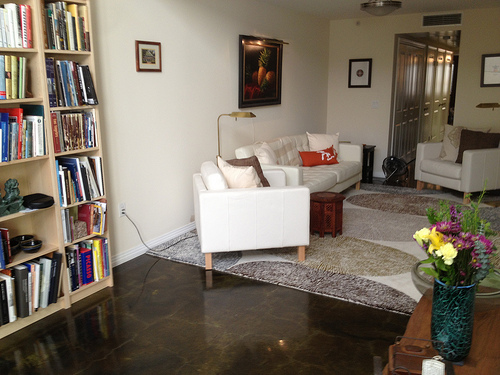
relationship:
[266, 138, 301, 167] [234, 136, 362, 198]
blanket on sofa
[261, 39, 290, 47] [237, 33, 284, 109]
light for art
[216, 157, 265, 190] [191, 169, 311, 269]
pillow on chair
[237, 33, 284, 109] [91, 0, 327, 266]
art hanging on wall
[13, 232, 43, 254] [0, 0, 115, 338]
bowls on book shelf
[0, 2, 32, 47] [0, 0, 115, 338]
books on book shelf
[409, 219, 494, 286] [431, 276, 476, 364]
flowers in vase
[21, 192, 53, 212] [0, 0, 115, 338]
cd case on book shelf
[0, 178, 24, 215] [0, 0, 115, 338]
chinese artwork on book shelf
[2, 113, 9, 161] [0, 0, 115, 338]
blue book on book shelf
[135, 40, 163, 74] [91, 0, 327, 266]
picture hanging on wall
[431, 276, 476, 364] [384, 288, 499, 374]
vase on table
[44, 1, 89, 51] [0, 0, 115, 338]
books in book shelf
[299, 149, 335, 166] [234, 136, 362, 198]
pillow on sofa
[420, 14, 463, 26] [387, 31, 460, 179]
air vent above doorway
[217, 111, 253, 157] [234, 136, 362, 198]
floor lamp behind sofa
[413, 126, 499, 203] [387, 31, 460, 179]
chair near doorway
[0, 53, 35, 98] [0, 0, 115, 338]
books on book shelf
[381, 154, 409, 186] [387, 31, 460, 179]
fan near doorway